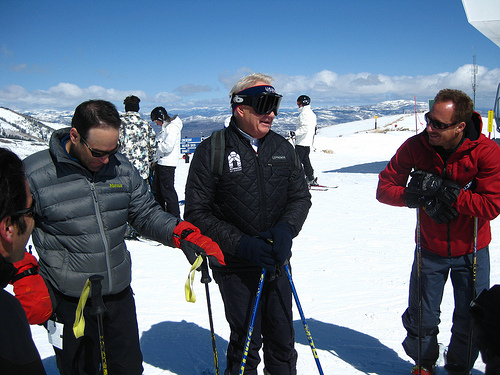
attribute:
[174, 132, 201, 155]
sign — blue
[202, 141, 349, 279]
coat — black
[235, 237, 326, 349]
ski poles — blue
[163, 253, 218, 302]
wrist traps — yellow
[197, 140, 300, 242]
wearing coat — white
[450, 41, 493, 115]
tree — leafless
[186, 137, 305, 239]
jacket — gray 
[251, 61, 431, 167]
mountain — ski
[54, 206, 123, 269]
jacket — man's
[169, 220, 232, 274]
mitten — red 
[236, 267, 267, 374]
ski poles — blue 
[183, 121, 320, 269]
coat — black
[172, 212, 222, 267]
glove — red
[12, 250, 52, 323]
glove — red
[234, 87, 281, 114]
goggles — large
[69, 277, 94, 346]
loop — yellow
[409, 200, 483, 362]
ski poles — black 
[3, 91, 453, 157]
mountains — snow covered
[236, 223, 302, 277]
mittens — blue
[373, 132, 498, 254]
coat — red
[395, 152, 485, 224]
gloves — black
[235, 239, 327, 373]
ski poles — blue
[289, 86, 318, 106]
helmet — black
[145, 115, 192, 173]
coats — white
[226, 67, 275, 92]
hair — grey